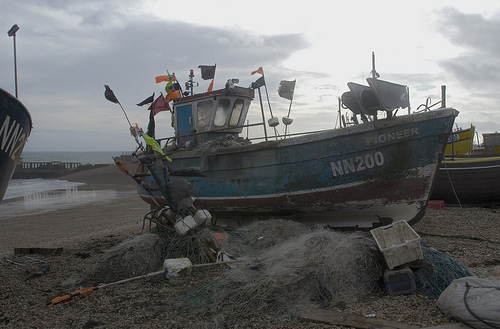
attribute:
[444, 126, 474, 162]
boat — yellow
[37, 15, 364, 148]
clouds — white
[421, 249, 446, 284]
netting — blue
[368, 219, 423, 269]
bin — white, empty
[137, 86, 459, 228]
boat — mostly blue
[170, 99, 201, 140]
door — blue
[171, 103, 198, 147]
door — blue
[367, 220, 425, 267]
crate — empty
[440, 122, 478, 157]
boat — yellow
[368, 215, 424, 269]
container — white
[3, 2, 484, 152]
sky — blue